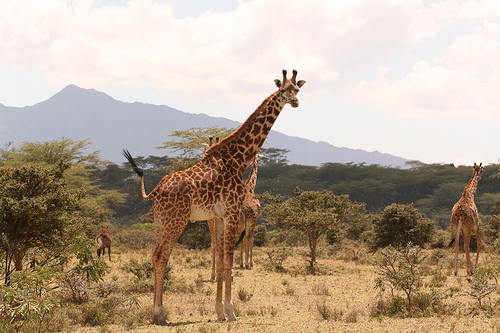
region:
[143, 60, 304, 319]
giraffe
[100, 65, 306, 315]
giraffe on plain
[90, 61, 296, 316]
spotted giraffe on plain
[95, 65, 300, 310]
brown and tan spotted giraffe on plain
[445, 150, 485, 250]
giraffe on plain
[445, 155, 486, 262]
spotted giraffe on plain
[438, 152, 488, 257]
brown and tan spotted giraffe on plain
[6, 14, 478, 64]
white clouds against blue sky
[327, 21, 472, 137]
white clouds against blue sky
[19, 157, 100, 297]
brown tree with green leaves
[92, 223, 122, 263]
horse on the plains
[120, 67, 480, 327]
two giraffes on the plains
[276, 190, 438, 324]
trees on the plains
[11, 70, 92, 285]
mountain in the background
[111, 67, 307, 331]
giraffe wagging tail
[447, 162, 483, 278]
giraffe walking to forest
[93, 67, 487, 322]
animals on the plains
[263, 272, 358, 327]
grass on the plains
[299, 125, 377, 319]
mountains, forest, and plains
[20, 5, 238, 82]
overcast skies over plains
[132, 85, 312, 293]
large adult giraffe facing a camera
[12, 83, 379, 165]
black silhouette of a mountain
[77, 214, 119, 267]
small baby giraffe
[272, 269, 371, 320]
sandy ground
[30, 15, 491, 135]
cloudy and overcast sky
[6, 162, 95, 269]
green coarse tree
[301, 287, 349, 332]
ground with sparse vegetation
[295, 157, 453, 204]
large expanse of dark green trees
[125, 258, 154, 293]
small bushes on the ground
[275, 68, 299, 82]
black tipped horns of giraffe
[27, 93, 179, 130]
the mountain is in the background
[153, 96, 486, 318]
the giraffes are four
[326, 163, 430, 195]
the trees are in the background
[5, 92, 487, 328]
the animals are in the wild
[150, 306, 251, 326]
the hoves are white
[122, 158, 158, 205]
the tail is up in the air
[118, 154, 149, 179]
the tail is black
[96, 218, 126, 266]
the animal is brown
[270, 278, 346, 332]
the grass is brown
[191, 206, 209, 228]
the belly is white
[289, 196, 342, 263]
brown tree with green leaves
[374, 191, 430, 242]
brown tree with green leaves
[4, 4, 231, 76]
white clouds against blue sky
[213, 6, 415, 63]
white clouds against blue sky